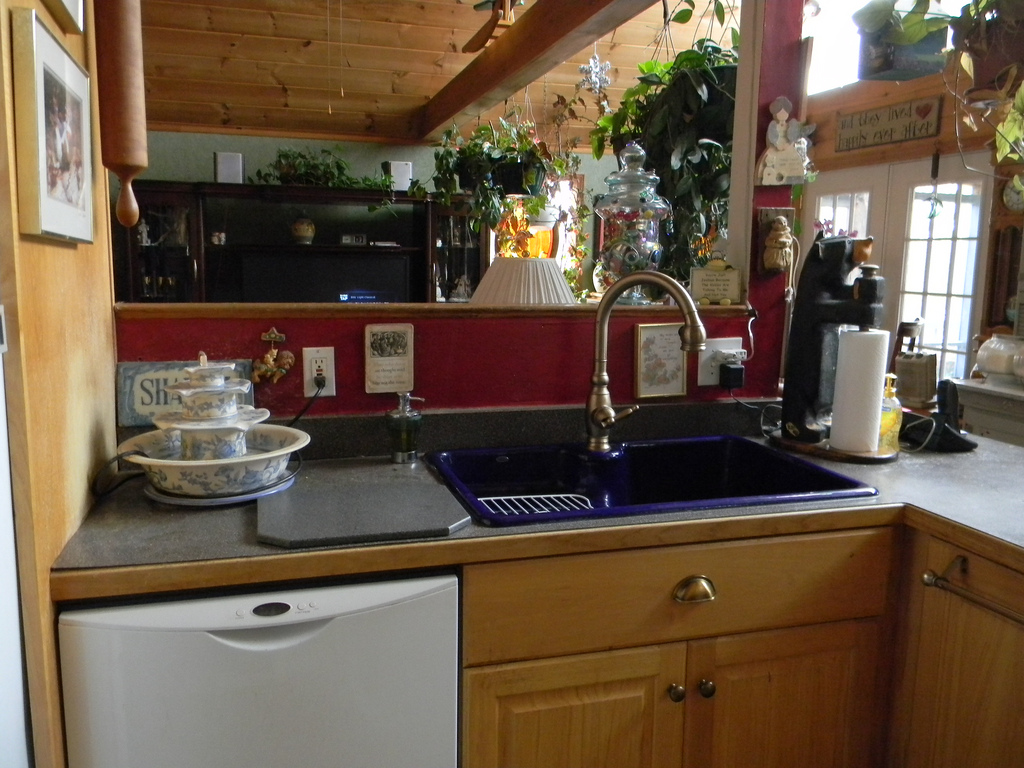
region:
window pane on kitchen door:
[831, 191, 849, 237]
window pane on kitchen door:
[848, 189, 872, 242]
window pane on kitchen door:
[927, 182, 961, 237]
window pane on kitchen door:
[893, 291, 923, 349]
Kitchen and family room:
[5, 37, 1023, 755]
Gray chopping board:
[247, 452, 476, 555]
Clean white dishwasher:
[44, 568, 474, 766]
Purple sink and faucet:
[424, 262, 884, 525]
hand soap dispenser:
[381, 383, 439, 469]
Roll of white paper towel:
[824, 318, 895, 461]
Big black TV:
[223, 236, 423, 300]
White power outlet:
[299, 342, 341, 401]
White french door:
[787, 146, 1003, 387]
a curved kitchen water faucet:
[590, 271, 707, 443]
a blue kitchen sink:
[434, 427, 880, 519]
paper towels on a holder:
[814, 301, 891, 466]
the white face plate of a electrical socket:
[304, 348, 337, 397]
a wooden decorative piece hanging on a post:
[754, 97, 813, 189]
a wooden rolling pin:
[90, 3, 147, 225]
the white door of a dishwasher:
[52, 579, 460, 764]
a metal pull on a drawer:
[668, 574, 720, 606]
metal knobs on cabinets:
[655, 650, 726, 709]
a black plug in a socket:
[299, 369, 337, 399]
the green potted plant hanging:
[453, 130, 542, 189]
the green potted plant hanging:
[621, 72, 688, 178]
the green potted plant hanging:
[949, 3, 1022, 191]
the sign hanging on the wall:
[827, 93, 949, 157]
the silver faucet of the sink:
[583, 266, 708, 463]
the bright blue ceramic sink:
[427, 418, 887, 546]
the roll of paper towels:
[833, 320, 885, 458]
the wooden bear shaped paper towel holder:
[784, 230, 890, 447]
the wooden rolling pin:
[92, 3, 146, 226]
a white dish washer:
[42, 556, 466, 766]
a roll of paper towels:
[832, 308, 890, 454]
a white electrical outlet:
[304, 348, 337, 402]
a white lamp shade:
[482, 247, 580, 308]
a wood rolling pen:
[87, 4, 158, 238]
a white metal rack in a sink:
[482, 490, 593, 514]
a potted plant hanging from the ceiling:
[485, 79, 542, 194]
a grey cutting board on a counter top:
[245, 484, 481, 543]